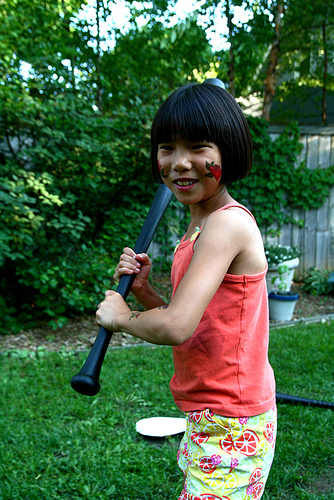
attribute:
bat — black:
[50, 89, 181, 369]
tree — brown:
[254, 0, 287, 141]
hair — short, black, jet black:
[167, 95, 276, 184]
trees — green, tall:
[13, 12, 127, 152]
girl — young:
[84, 71, 292, 498]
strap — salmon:
[220, 203, 267, 231]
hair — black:
[149, 81, 252, 184]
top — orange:
[169, 203, 280, 411]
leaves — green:
[3, 344, 72, 371]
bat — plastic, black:
[68, 76, 226, 396]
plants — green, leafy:
[257, 136, 325, 227]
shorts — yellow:
[167, 400, 286, 498]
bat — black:
[281, 383, 332, 423]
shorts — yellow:
[171, 411, 285, 498]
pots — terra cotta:
[264, 243, 301, 321]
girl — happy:
[92, 81, 279, 498]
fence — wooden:
[151, 131, 332, 284]